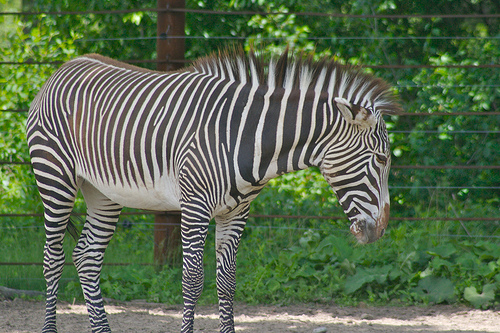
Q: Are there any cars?
A: No, there are no cars.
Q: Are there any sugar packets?
A: No, there are no sugar packets.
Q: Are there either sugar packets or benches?
A: No, there are no sugar packets or benches.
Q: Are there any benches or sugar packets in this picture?
A: No, there are no sugar packets or benches.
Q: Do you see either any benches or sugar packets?
A: No, there are no sugar packets or benches.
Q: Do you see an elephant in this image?
A: No, there are no elephants.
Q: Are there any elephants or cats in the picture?
A: No, there are no elephants or cats.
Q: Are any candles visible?
A: No, there are no candles.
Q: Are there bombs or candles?
A: No, there are no candles or bombs.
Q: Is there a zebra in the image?
A: Yes, there is a zebra.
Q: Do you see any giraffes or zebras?
A: Yes, there is a zebra.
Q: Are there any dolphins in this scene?
A: No, there are no dolphins.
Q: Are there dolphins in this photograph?
A: No, there are no dolphins.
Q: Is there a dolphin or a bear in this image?
A: No, there are no dolphins or bears.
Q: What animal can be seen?
A: The animal is a zebra.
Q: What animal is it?
A: The animal is a zebra.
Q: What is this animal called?
A: This is a zebra.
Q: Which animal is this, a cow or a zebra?
A: This is a zebra.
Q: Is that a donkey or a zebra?
A: That is a zebra.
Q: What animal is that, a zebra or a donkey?
A: That is a zebra.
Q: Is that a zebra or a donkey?
A: That is a zebra.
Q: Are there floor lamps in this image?
A: No, there are no floor lamps.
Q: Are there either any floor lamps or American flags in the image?
A: No, there are no floor lamps or American flags.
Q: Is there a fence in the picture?
A: Yes, there is a fence.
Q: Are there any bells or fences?
A: Yes, there is a fence.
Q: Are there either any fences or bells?
A: Yes, there is a fence.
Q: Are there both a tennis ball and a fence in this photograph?
A: No, there is a fence but no tennis balls.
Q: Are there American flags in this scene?
A: No, there are no American flags.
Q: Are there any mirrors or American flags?
A: No, there are no American flags or mirrors.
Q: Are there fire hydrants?
A: No, there are no fire hydrants.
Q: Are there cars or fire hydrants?
A: No, there are no fire hydrants or cars.